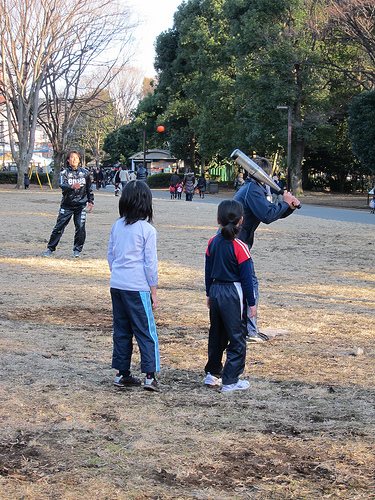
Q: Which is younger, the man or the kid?
A: The kid is younger than the man.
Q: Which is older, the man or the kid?
A: The man is older than the kid.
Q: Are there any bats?
A: Yes, there is a bat.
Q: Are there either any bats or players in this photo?
A: Yes, there is a bat.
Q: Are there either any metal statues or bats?
A: Yes, there is a metal bat.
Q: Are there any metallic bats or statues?
A: Yes, there is a metal bat.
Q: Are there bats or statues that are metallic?
A: Yes, the bat is metallic.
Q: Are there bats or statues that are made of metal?
A: Yes, the bat is made of metal.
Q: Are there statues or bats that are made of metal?
A: Yes, the bat is made of metal.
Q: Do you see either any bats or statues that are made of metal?
A: Yes, the bat is made of metal.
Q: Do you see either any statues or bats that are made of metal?
A: Yes, the bat is made of metal.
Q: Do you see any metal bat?
A: Yes, there is a metal bat.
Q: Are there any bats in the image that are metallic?
A: Yes, there is a bat that is metallic.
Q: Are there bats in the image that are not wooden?
A: Yes, there is a metallic bat.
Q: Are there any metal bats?
A: Yes, there is a bat that is made of metal.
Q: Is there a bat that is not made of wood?
A: Yes, there is a bat that is made of metal.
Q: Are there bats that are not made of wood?
A: Yes, there is a bat that is made of metal.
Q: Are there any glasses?
A: No, there are no glasses.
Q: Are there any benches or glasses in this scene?
A: No, there are no glasses or benches.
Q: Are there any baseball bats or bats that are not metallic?
A: No, there is a bat but it is metallic.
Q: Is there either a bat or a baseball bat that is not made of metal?
A: No, there is a bat but it is made of metal.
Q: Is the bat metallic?
A: Yes, the bat is metallic.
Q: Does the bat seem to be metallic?
A: Yes, the bat is metallic.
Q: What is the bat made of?
A: The bat is made of metal.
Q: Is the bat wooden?
A: No, the bat is metallic.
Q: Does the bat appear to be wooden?
A: No, the bat is metallic.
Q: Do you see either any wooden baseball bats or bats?
A: No, there is a bat but it is metallic.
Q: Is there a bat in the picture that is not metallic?
A: No, there is a bat but it is metallic.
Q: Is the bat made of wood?
A: No, the bat is made of metal.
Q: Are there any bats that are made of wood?
A: No, there is a bat but it is made of metal.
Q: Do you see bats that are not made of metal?
A: No, there is a bat but it is made of metal.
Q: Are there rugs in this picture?
A: No, there are no rugs.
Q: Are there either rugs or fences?
A: No, there are no rugs or fences.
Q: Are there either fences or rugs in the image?
A: No, there are no rugs or fences.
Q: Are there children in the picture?
A: Yes, there is a child.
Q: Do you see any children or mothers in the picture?
A: Yes, there is a child.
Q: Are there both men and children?
A: Yes, there are both a child and a man.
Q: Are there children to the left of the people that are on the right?
A: Yes, there is a child to the left of the people.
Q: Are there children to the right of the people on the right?
A: No, the child is to the left of the people.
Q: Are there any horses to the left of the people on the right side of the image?
A: No, there is a child to the left of the people.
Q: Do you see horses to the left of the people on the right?
A: No, there is a child to the left of the people.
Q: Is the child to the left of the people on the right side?
A: Yes, the child is to the left of the people.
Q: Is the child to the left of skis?
A: No, the child is to the left of the people.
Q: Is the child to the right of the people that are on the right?
A: No, the child is to the left of the people.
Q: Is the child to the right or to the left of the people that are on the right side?
A: The child is to the left of the people.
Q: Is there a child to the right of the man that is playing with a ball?
A: Yes, there is a child to the right of the man.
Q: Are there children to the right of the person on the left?
A: Yes, there is a child to the right of the man.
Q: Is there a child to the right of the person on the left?
A: Yes, there is a child to the right of the man.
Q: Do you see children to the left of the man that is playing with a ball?
A: No, the child is to the right of the man.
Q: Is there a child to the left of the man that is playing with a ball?
A: No, the child is to the right of the man.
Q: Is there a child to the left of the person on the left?
A: No, the child is to the right of the man.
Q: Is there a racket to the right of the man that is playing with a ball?
A: No, there is a child to the right of the man.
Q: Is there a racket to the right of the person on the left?
A: No, there is a child to the right of the man.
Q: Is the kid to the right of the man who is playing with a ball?
A: Yes, the kid is to the right of the man.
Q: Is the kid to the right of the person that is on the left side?
A: Yes, the kid is to the right of the man.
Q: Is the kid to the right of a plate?
A: No, the kid is to the right of the man.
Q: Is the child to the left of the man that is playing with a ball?
A: No, the child is to the right of the man.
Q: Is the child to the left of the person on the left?
A: No, the child is to the right of the man.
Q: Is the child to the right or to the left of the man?
A: The child is to the right of the man.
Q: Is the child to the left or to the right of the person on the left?
A: The child is to the right of the man.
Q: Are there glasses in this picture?
A: No, there are no glasses.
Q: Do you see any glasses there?
A: No, there are no glasses.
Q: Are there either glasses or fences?
A: No, there are no glasses or fences.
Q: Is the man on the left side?
A: Yes, the man is on the left of the image.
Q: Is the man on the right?
A: No, the man is on the left of the image.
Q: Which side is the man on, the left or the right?
A: The man is on the left of the image.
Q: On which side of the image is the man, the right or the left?
A: The man is on the left of the image.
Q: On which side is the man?
A: The man is on the left of the image.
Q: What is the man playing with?
A: The man is playing with a ball.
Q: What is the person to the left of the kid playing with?
A: The man is playing with a ball.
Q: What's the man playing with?
A: The man is playing with a ball.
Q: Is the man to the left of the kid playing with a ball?
A: Yes, the man is playing with a ball.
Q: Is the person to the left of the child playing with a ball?
A: Yes, the man is playing with a ball.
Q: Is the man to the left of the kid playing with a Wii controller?
A: No, the man is playing with a ball.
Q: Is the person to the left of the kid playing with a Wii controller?
A: No, the man is playing with a ball.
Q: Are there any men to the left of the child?
A: Yes, there is a man to the left of the child.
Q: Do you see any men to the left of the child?
A: Yes, there is a man to the left of the child.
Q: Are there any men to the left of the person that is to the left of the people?
A: Yes, there is a man to the left of the child.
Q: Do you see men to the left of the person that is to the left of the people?
A: Yes, there is a man to the left of the child.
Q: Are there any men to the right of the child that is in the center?
A: No, the man is to the left of the kid.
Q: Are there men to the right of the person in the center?
A: No, the man is to the left of the kid.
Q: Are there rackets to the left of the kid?
A: No, there is a man to the left of the kid.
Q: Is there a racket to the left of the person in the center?
A: No, there is a man to the left of the kid.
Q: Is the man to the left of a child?
A: Yes, the man is to the left of a child.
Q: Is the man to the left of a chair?
A: No, the man is to the left of a child.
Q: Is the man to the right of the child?
A: No, the man is to the left of the child.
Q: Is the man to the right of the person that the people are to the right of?
A: No, the man is to the left of the child.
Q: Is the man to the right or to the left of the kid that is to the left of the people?
A: The man is to the left of the child.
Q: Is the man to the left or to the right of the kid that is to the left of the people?
A: The man is to the left of the child.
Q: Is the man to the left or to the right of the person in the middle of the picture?
A: The man is to the left of the child.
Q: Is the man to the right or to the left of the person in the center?
A: The man is to the left of the child.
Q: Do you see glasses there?
A: No, there are no glasses.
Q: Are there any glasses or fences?
A: No, there are no glasses or fences.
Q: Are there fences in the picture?
A: No, there are no fences.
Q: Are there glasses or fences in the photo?
A: No, there are no fences or glasses.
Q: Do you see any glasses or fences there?
A: No, there are no fences or glasses.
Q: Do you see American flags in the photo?
A: No, there are no American flags.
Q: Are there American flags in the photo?
A: No, there are no American flags.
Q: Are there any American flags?
A: No, there are no American flags.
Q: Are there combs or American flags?
A: No, there are no American flags or combs.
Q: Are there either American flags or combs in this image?
A: No, there are no American flags or combs.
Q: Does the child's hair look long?
A: Yes, the hair is long.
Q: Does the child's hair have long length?
A: Yes, the hair is long.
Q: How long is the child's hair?
A: The hair is long.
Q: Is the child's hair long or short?
A: The hair is long.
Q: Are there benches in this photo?
A: No, there are no benches.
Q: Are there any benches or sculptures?
A: No, there are no benches or sculptures.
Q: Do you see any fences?
A: No, there are no fences.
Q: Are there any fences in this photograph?
A: No, there are no fences.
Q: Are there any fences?
A: No, there are no fences.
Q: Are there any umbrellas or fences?
A: No, there are no fences or umbrellas.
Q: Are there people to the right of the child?
A: Yes, there are people to the right of the child.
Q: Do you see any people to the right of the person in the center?
A: Yes, there are people to the right of the child.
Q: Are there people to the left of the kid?
A: No, the people are to the right of the kid.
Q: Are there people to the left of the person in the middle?
A: No, the people are to the right of the kid.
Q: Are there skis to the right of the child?
A: No, there are people to the right of the child.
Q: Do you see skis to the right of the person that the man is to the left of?
A: No, there are people to the right of the child.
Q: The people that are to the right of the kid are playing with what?
A: The people are playing with a ball.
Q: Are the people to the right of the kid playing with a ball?
A: Yes, the people are playing with a ball.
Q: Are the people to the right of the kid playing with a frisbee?
A: No, the people are playing with a ball.